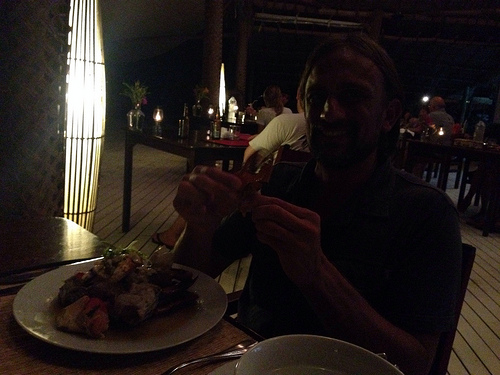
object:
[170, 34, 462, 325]
man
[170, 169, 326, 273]
hands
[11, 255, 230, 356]
plate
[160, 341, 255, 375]
utensils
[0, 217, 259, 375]
table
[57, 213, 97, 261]
reflections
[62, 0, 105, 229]
light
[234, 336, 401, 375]
bowl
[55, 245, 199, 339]
food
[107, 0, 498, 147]
background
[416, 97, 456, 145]
people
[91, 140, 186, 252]
floor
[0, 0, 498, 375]
restaurant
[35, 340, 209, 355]
white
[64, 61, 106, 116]
bright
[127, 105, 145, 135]
vase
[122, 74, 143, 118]
plant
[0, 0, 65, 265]
brown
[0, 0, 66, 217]
fence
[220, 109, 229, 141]
glass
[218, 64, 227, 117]
candle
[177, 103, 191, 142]
wine glass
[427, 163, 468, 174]
carpet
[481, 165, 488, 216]
black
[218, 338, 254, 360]
handle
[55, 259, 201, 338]
meats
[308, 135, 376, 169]
beard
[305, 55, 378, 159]
face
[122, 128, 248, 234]
wood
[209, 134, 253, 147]
place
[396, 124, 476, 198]
tables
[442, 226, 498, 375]
floors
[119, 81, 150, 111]
flower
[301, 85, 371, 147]
smiling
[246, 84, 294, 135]
couple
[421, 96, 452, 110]
bald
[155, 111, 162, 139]
lit